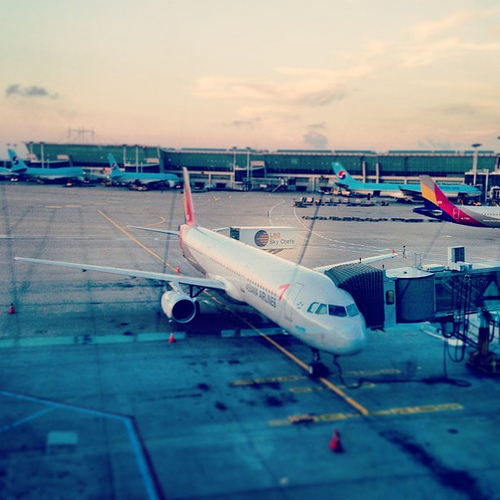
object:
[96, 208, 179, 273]
line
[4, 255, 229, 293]
wing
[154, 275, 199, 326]
engine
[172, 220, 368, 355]
fuselage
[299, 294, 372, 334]
cock pit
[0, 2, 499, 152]
sky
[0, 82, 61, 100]
cloud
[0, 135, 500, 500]
airport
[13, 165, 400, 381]
airplane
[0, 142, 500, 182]
building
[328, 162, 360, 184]
plane's tail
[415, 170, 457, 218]
plane's tail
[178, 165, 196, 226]
plane's tail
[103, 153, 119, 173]
plane's tail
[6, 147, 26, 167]
plane's tail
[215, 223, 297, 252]
truck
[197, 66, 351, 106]
clouds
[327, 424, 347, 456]
caution cone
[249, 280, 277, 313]
company name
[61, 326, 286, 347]
line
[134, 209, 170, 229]
line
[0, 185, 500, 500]
pavement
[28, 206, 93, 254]
gray concrete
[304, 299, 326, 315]
windows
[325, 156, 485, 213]
airplane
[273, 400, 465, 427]
line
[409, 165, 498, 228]
plane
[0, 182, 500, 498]
tarmac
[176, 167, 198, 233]
wing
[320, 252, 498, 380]
gate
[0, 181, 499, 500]
surface